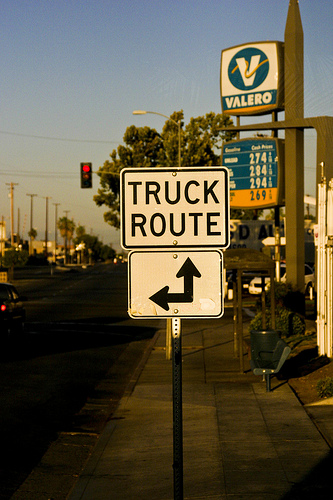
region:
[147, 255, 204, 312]
Black arrows on black and white sign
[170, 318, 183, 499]
Thin metal pole holding black and white traffic signs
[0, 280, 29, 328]
Car is parked in front of traffic light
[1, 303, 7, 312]
Red light on car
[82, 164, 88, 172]
Red light on traffic light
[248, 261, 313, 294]
White van is parked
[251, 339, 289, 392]
Green metal bench next to green metal trash can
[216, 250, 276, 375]
Bus stop near gas station sign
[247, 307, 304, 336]
Small green bush near gas station sign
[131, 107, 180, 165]
Light post near traffic light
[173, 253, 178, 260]
Small silver screw near black arrows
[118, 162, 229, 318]
Traffic sign is black and white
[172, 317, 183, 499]
Metal pole holding black and white traffic signs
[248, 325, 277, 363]
Green metal trash can next to bus stop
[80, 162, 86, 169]
Red light on black traffic light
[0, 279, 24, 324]
Car parked in front of traffic light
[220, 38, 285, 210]
Large gas station sign near bus stop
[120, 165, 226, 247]
the white sign that says TRUCK ROUTE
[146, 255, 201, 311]
the black arrows on the white sign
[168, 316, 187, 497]
the pole to hold up signs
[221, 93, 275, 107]
the word VALERO on the sign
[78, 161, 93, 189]
the red traffic light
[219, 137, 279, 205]
the sign that displays gas prices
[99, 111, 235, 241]
the green leaves on the tree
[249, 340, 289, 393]
the green bench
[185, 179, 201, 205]
the black letter C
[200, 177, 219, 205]
the black letter K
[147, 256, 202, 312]
Black arrow on black and white traffic sign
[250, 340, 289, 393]
Metal green bench next to metal green trash can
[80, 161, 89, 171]
Red light on black traffic light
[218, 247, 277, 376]
Bus stop next to green metal trash can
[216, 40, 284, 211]
Large gas station sign near traffic light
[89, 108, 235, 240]
Large tree behind traffic light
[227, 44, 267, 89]
Large teal circle on gas station sign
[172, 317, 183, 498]
black metal post under sign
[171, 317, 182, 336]
white area on post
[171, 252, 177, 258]
silver rivets on sign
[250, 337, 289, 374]
green bench on sidewalk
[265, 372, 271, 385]
black post supporting bench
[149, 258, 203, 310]
black arrow on sign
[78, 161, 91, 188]
traffic light over street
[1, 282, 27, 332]
car on street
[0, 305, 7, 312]
red tail light on car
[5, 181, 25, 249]
wooden utility pole